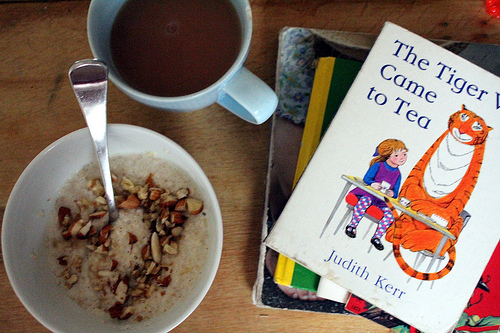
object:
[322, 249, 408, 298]
author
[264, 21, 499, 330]
cover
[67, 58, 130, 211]
utensil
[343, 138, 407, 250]
girl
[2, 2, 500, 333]
table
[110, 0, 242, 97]
coffee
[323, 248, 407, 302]
word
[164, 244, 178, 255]
pecans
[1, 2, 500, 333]
table top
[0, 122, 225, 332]
bowl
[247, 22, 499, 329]
stack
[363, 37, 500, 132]
title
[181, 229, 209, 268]
oatmeal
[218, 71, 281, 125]
handle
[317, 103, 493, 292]
picture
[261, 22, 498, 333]
book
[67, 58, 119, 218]
spoon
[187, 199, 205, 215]
nuts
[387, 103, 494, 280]
tiger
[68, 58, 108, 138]
spoon handle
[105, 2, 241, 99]
liquid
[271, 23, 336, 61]
book corner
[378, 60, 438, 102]
word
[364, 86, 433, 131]
word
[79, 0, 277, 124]
cup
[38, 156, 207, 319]
food